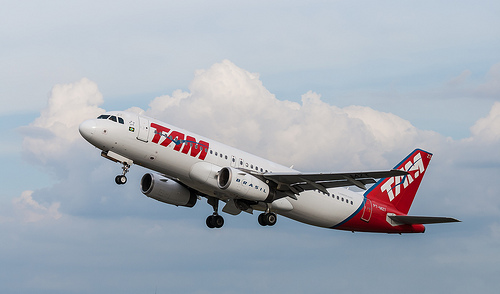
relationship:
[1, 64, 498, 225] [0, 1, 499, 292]
cloud in sky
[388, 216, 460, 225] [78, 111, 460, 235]
tail wing of airplane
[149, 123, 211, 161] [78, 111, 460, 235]
logo on airplane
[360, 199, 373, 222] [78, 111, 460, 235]
rear door on airplane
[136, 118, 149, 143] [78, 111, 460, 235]
front door on airplane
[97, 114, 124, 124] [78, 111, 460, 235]
cockpit window on airplane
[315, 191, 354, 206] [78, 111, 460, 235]
passenger windows on airplane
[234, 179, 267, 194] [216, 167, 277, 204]
letters on engine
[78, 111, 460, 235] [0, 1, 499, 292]
airplane in sky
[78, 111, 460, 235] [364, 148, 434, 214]
airplane has a tail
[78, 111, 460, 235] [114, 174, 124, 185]
airplane has wheels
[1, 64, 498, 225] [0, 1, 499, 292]
cloud against sky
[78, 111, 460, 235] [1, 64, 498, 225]
airplane in front of cloud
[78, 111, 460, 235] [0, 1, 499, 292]
airplane in front of sky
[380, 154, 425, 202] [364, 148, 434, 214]
tam on tail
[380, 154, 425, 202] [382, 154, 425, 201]
tam says tam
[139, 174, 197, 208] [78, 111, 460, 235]
engine on airplane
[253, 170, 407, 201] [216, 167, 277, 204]
wing behind engine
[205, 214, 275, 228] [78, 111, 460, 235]
back wheels of airplane